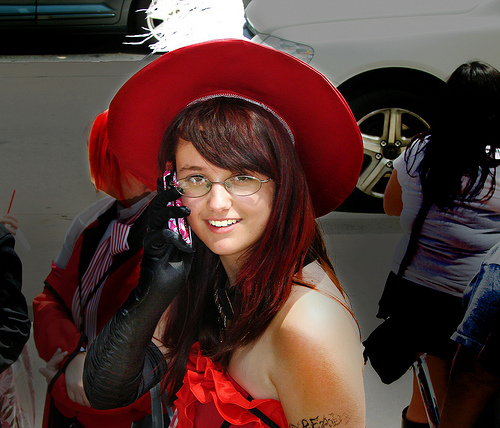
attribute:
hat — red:
[73, 30, 376, 244]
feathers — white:
[134, 0, 296, 85]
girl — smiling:
[164, 158, 343, 311]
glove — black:
[62, 198, 187, 400]